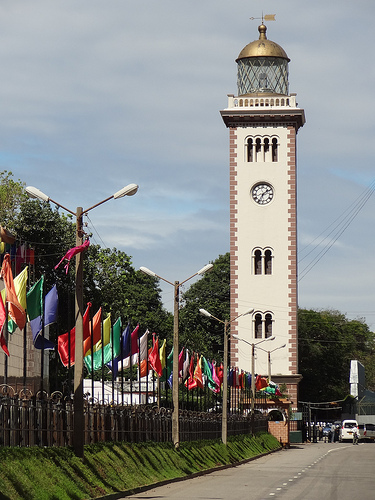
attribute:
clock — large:
[253, 181, 272, 204]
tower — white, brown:
[217, 137, 317, 348]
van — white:
[336, 420, 362, 442]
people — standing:
[301, 420, 344, 441]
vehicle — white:
[340, 420, 361, 443]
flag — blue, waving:
[29, 281, 60, 350]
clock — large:
[246, 180, 276, 205]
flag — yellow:
[10, 266, 29, 311]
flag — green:
[74, 305, 143, 401]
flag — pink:
[130, 321, 137, 352]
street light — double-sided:
[19, 178, 145, 456]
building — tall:
[219, 4, 304, 440]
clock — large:
[253, 180, 277, 206]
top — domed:
[228, 9, 292, 107]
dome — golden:
[234, 24, 290, 65]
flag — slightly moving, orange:
[0, 252, 30, 343]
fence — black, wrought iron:
[1, 249, 268, 442]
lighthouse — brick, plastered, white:
[191, 29, 349, 425]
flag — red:
[53, 299, 92, 367]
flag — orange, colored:
[0, 252, 25, 325]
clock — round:
[242, 174, 293, 219]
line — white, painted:
[268, 490, 276, 496]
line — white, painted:
[275, 485, 281, 491]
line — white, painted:
[281, 481, 288, 487]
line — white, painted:
[288, 477, 292, 482]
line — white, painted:
[296, 471, 302, 475]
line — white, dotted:
[267, 441, 363, 495]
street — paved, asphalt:
[107, 439, 363, 498]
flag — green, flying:
[84, 315, 121, 373]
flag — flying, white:
[106, 328, 151, 375]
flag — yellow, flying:
[1, 264, 29, 314]